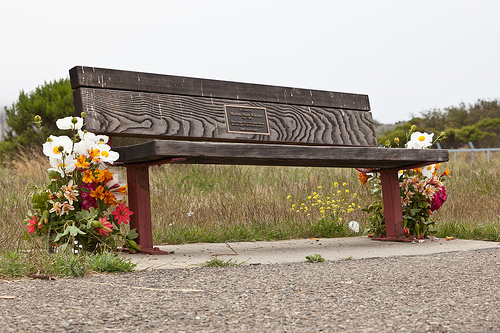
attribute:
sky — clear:
[0, 0, 499, 125]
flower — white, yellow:
[404, 129, 434, 151]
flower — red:
[110, 195, 135, 228]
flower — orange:
[80, 167, 97, 186]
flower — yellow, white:
[403, 128, 436, 149]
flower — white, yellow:
[40, 131, 74, 161]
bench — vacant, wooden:
[68, 63, 449, 255]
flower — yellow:
[284, 192, 292, 200]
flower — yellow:
[315, 184, 324, 190]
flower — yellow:
[331, 179, 340, 189]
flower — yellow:
[340, 181, 349, 188]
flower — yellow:
[349, 200, 358, 207]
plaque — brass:
[224, 104, 272, 135]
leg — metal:
[371, 170, 413, 240]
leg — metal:
[124, 162, 168, 256]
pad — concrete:
[116, 233, 496, 271]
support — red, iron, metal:
[374, 171, 414, 241]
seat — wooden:
[112, 139, 446, 166]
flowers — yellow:
[288, 180, 362, 220]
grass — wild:
[2, 150, 499, 277]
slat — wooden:
[72, 86, 374, 143]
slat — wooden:
[122, 139, 450, 165]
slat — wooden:
[124, 134, 449, 167]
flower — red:
[111, 200, 135, 226]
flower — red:
[24, 212, 40, 234]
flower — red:
[93, 216, 114, 237]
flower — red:
[75, 180, 96, 207]